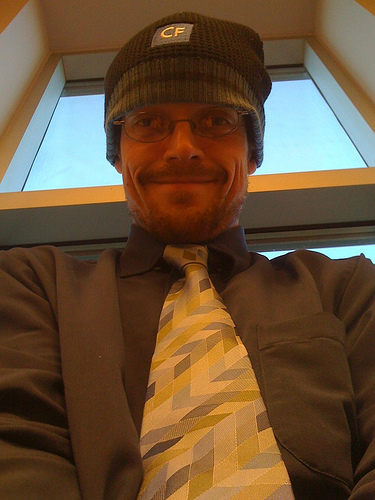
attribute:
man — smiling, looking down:
[1, 13, 373, 496]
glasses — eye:
[110, 104, 253, 141]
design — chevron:
[145, 359, 263, 413]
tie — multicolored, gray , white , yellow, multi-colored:
[138, 263, 295, 496]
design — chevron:
[143, 327, 234, 411]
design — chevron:
[156, 271, 215, 340]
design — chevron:
[142, 399, 274, 499]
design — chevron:
[164, 244, 209, 265]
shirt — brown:
[0, 219, 373, 498]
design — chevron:
[170, 369, 257, 485]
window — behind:
[22, 66, 374, 263]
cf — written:
[162, 27, 195, 43]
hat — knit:
[71, 12, 289, 130]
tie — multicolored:
[141, 242, 295, 498]